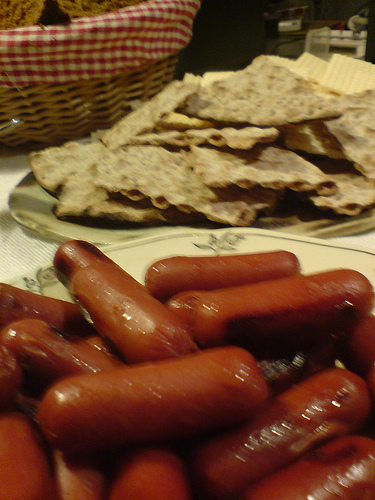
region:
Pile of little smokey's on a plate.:
[1, 238, 365, 496]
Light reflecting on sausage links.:
[158, 390, 373, 488]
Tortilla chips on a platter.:
[32, 60, 372, 225]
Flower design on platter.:
[193, 229, 242, 256]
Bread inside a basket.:
[0, 0, 150, 25]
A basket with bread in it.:
[2, 0, 200, 145]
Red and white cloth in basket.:
[2, 3, 198, 84]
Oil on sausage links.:
[3, 299, 299, 466]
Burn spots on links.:
[219, 295, 354, 384]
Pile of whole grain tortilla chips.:
[29, 64, 370, 223]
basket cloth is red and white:
[0, 0, 198, 90]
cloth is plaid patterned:
[0, 0, 203, 90]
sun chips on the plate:
[26, 33, 368, 243]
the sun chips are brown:
[22, 65, 368, 222]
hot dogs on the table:
[1, 194, 372, 494]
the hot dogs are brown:
[1, 222, 361, 496]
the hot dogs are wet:
[1, 225, 373, 489]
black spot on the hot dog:
[309, 443, 367, 475]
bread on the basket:
[1, 0, 151, 36]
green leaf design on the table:
[186, 226, 255, 273]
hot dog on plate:
[8, 236, 372, 496]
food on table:
[2, 25, 369, 493]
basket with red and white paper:
[2, 0, 206, 152]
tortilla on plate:
[15, 43, 369, 238]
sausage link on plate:
[4, 234, 370, 497]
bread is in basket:
[6, 4, 202, 152]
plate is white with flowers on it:
[0, 233, 372, 497]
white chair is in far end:
[296, 11, 368, 59]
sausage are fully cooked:
[0, 228, 370, 494]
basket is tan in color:
[0, 0, 203, 158]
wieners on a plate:
[0, 220, 368, 498]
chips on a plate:
[13, 61, 370, 239]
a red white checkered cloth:
[0, 0, 189, 86]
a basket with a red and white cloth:
[3, 2, 195, 148]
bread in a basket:
[5, 1, 187, 143]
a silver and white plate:
[40, 223, 373, 300]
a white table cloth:
[0, 149, 43, 274]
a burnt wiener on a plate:
[173, 267, 373, 344]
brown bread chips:
[35, 66, 373, 221]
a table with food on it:
[3, 1, 363, 494]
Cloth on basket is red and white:
[0, 0, 203, 84]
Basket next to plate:
[1, 0, 196, 148]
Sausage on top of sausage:
[38, 348, 274, 449]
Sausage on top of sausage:
[141, 248, 301, 298]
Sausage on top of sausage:
[193, 265, 373, 344]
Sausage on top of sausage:
[193, 369, 370, 493]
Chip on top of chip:
[199, 69, 340, 124]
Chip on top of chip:
[92, 150, 254, 220]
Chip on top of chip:
[190, 143, 341, 193]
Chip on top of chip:
[26, 138, 115, 191]